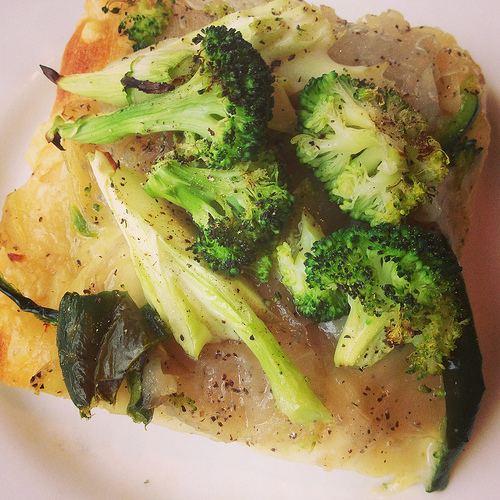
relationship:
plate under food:
[4, 9, 489, 494] [41, 39, 467, 442]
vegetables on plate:
[61, 40, 461, 457] [4, 9, 489, 494]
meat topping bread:
[331, 27, 445, 128] [51, 0, 120, 114]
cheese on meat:
[0, 204, 98, 296] [48, 10, 497, 446]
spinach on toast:
[111, 190, 208, 305] [45, 36, 475, 484]